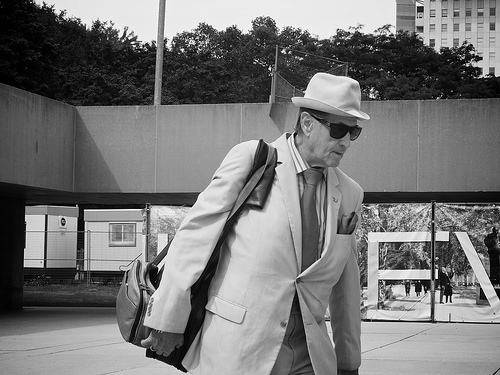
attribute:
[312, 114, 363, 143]
sunglasses — black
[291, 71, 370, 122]
hat — white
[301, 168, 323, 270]
tie — long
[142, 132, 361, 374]
suit — white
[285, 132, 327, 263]
shirt — striped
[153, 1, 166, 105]
pole — grey, tall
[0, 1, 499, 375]
photo — black, white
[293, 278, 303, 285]
buttons — buttoned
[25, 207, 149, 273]
trailers — white